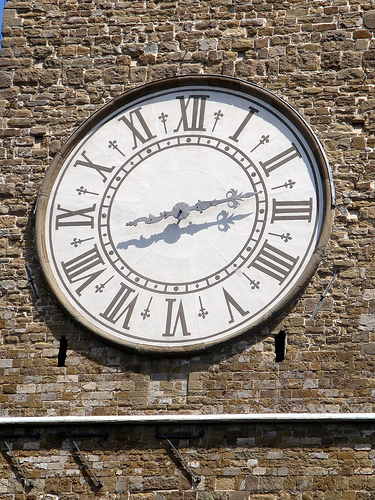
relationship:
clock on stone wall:
[20, 70, 343, 360] [1, 0, 375, 499]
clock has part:
[123, 189, 262, 236] [187, 353, 195, 366]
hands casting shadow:
[123, 185, 264, 227] [115, 200, 256, 249]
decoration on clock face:
[75, 186, 98, 196] [30, 107, 341, 327]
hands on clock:
[115, 210, 254, 251] [20, 70, 343, 360]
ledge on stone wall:
[1, 411, 374, 427] [1, 0, 372, 498]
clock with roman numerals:
[33, 74, 337, 355] [43, 90, 317, 340]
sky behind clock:
[0, 2, 3, 21] [20, 70, 343, 360]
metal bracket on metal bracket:
[146, 424, 219, 487] [51, 431, 113, 488]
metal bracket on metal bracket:
[146, 424, 219, 487] [0, 421, 45, 490]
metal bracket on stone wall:
[146, 424, 219, 487] [31, 331, 289, 498]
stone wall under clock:
[1, 0, 375, 499] [20, 70, 343, 360]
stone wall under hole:
[1, 0, 375, 499] [261, 323, 295, 372]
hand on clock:
[121, 188, 253, 229] [36, 80, 328, 353]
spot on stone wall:
[273, 329, 286, 363] [1, 0, 375, 499]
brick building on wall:
[2, 1, 374, 497] [1, 1, 373, 413]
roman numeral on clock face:
[270, 197, 312, 223] [43, 85, 324, 348]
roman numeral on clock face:
[54, 203, 95, 230] [43, 85, 324, 348]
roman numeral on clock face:
[98, 281, 138, 331] [43, 85, 324, 348]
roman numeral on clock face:
[247, 238, 298, 285] [43, 85, 324, 348]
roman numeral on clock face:
[219, 283, 250, 323] [43, 85, 324, 348]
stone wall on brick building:
[1, 0, 375, 499] [2, 1, 374, 497]